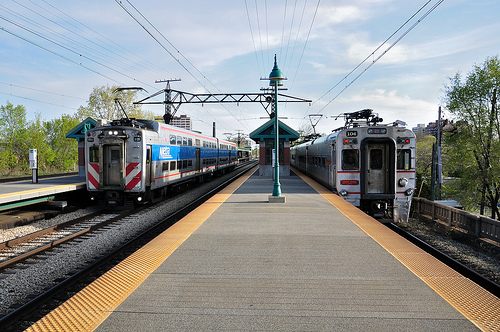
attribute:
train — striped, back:
[82, 135, 159, 209]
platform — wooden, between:
[202, 216, 330, 293]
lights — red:
[342, 129, 420, 154]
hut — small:
[247, 113, 344, 178]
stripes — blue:
[146, 138, 240, 161]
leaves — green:
[28, 106, 78, 158]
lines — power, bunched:
[236, 2, 322, 44]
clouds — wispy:
[168, 18, 319, 63]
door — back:
[105, 147, 138, 184]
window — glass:
[90, 149, 105, 162]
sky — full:
[89, 5, 392, 88]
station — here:
[178, 90, 493, 253]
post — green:
[269, 123, 303, 187]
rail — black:
[46, 280, 102, 306]